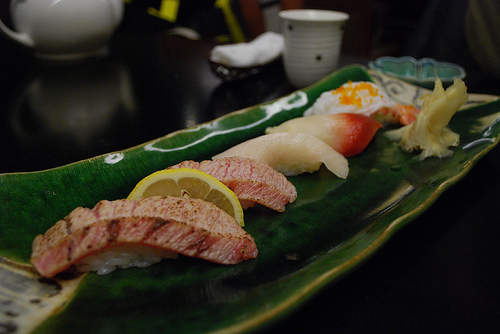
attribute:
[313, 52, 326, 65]
spot — black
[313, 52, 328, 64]
circle — black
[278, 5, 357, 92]
cup — white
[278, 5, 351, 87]
cup — white, small, plastic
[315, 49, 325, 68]
circle — black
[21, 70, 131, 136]
surface — black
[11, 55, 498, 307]
plate — green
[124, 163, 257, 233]
slice — lemon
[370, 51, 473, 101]
bowl — small, glass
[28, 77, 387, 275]
sea food — fancy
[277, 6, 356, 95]
glass — white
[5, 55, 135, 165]
reflection — pot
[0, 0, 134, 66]
pot — white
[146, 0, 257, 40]
object — yellow, black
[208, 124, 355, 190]
sushi — tan, piece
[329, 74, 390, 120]
topping — orange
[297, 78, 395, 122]
creme — white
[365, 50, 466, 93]
bowl — small, green, dipping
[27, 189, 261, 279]
beef — sliced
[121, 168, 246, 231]
orange — ripe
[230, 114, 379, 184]
pineapple — sliced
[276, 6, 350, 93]
cut — white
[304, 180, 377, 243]
veggie — green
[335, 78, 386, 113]
cheese — yellow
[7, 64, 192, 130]
table — dark, wood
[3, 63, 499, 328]
dish — long, green, rectangular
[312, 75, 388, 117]
sauce — white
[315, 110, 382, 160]
shrimp — pink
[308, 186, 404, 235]
dish — wave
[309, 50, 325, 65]
hole — small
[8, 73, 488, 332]
plate — green 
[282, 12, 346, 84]
cup — white 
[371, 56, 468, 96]
bowl — green 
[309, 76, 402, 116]
sprinkle — orange 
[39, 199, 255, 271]
meat — grilled 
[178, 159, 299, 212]
meat — grilled 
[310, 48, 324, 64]
dot — black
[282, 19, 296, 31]
dot — black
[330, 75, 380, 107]
zest — orange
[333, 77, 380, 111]
zest — orange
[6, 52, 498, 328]
platter — long, green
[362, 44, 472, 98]
bowl — small, green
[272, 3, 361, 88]
cup — white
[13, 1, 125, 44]
pitcher — white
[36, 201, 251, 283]
meat — grilled slice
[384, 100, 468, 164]
ginger — wedge